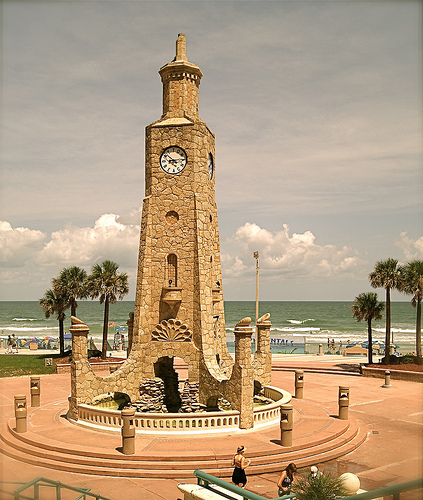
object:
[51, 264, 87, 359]
palm tree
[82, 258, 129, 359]
palm tree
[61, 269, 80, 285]
leaves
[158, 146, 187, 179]
clock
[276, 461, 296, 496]
woman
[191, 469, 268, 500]
metal guardrail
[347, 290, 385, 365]
palm trees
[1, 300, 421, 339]
sea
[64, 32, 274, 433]
clock tower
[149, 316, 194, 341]
design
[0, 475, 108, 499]
guard railing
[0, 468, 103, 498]
railing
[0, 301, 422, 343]
water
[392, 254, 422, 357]
trees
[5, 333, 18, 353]
couple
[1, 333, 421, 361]
beach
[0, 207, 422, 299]
cloud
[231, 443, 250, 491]
woman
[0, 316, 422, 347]
waves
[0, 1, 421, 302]
sky